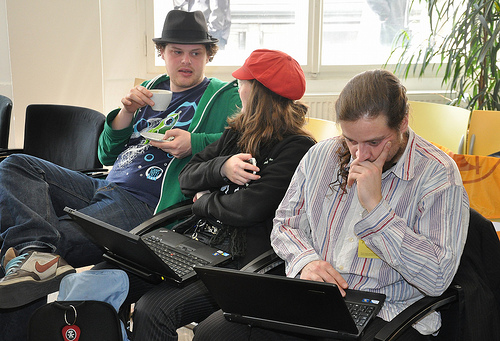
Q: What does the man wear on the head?
A: A black hat.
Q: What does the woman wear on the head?
A: A red hat.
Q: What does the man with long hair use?
A: A laptop.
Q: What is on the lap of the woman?
A: A laptop.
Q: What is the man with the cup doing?
A: Talking.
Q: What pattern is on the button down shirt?
A: Stripes.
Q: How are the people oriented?
A: Seated.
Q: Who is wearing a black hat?
A: A man.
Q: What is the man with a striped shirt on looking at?
A: A computer.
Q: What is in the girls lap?
A: A computer.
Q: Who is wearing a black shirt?
A: A girl.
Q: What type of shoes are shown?
A: Tennis shoes.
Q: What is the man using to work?
A: A laptop.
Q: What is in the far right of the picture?
A: A tree.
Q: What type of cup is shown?
A: A tea cup.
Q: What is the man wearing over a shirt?
A: A jacket.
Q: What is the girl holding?
A: A laptop.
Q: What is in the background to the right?
A: A plant.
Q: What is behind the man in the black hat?
A: A window.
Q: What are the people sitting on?
A: Chairs.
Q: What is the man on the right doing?
A: Working on a laptop.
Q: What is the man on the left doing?
A: Drinking coffee.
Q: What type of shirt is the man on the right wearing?
A: Long sleeved stripes.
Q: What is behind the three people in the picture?
A: Chairs.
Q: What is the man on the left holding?
A: A tea cup.